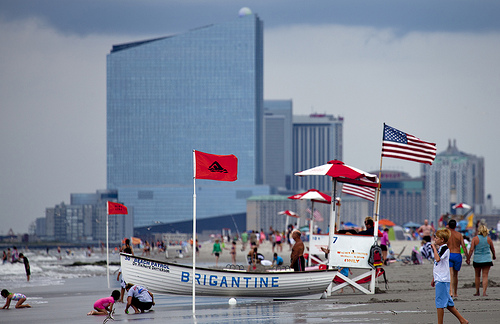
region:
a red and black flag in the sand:
[183, 143, 243, 321]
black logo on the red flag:
[205, 159, 234, 177]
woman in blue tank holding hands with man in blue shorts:
[445, 219, 498, 298]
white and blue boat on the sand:
[115, 245, 353, 297]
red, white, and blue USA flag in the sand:
[373, 122, 448, 289]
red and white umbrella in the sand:
[294, 154, 384, 299]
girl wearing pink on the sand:
[83, 282, 128, 318]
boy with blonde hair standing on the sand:
[418, 226, 488, 322]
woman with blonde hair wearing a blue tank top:
[465, 219, 498, 305]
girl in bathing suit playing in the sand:
[3, 285, 42, 312]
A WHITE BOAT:
[95, 243, 357, 298]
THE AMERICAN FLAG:
[371, 120, 443, 292]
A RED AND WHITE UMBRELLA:
[296, 143, 379, 196]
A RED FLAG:
[177, 141, 244, 241]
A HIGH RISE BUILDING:
[84, 3, 288, 240]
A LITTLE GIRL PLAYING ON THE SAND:
[1, 278, 38, 314]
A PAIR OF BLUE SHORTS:
[426, 278, 470, 310]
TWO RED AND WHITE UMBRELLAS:
[278, 154, 377, 206]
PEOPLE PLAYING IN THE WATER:
[41, 236, 114, 263]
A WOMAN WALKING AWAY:
[467, 220, 494, 299]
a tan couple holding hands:
[440, 217, 498, 297]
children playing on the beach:
[3, 278, 158, 319]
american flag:
[371, 110, 436, 270]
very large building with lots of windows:
[94, 12, 270, 234]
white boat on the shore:
[106, 238, 351, 302]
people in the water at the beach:
[0, 240, 105, 282]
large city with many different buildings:
[14, 9, 496, 241]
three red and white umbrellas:
[269, 156, 374, 251]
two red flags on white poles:
[88, 151, 244, 304]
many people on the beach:
[13, 207, 498, 315]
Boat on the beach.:
[108, 230, 387, 300]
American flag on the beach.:
[358, 105, 470, 217]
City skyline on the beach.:
[48, 64, 396, 276]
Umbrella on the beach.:
[286, 132, 398, 217]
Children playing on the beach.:
[62, 266, 148, 320]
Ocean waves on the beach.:
[17, 217, 122, 318]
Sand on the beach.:
[290, 277, 382, 317]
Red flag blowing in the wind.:
[143, 135, 255, 247]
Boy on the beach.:
[414, 206, 461, 291]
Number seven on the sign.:
[316, 205, 355, 246]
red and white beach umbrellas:
[287, 155, 378, 264]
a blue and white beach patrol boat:
[116, 251, 341, 303]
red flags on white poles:
[93, 143, 240, 322]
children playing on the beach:
[86, 278, 158, 319]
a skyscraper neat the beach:
[96, 11, 272, 236]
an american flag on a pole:
[371, 109, 444, 172]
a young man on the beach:
[426, 227, 468, 322]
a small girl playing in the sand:
[1, 277, 43, 314]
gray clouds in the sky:
[3, 2, 498, 40]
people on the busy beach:
[1, 217, 499, 321]